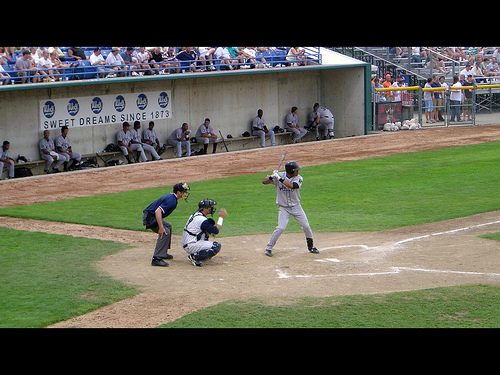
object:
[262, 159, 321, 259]
batter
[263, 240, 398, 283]
batter's box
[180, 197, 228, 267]
catcher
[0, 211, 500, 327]
dirt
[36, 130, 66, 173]
player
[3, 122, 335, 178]
bench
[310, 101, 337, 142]
player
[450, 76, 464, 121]
spectator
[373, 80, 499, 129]
fence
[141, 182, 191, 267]
umpire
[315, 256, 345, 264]
plate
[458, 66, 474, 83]
spectator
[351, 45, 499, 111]
stands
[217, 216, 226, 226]
band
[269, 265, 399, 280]
line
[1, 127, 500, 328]
field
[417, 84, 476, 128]
gate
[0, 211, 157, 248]
path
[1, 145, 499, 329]
grass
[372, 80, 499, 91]
guard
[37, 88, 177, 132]
banner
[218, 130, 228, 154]
bat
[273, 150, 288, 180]
bat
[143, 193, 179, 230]
shirt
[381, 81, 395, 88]
shirt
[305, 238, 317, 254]
shin guard